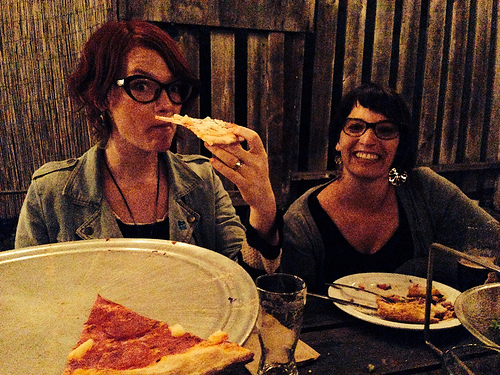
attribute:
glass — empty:
[257, 273, 308, 374]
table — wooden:
[301, 304, 475, 375]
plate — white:
[329, 271, 465, 329]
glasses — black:
[116, 75, 195, 105]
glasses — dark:
[341, 117, 404, 140]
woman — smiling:
[280, 84, 499, 274]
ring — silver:
[234, 158, 244, 170]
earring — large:
[388, 168, 408, 187]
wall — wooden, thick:
[1, 2, 498, 213]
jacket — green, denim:
[16, 141, 122, 248]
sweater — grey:
[397, 167, 500, 275]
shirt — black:
[309, 192, 413, 292]